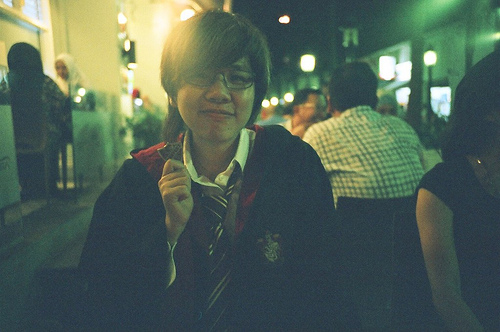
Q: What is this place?
A: Restaurant.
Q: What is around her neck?
A: A tie.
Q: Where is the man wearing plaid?
A: Behind her.